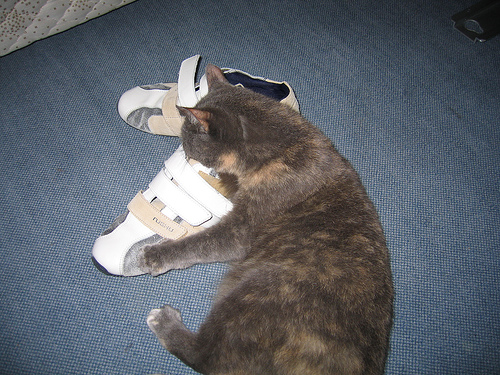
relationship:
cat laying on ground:
[134, 62, 397, 375] [7, 4, 496, 374]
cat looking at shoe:
[141, 62, 397, 373] [98, 140, 230, 269]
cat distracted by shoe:
[141, 62, 397, 373] [91, 140, 241, 282]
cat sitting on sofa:
[141, 62, 397, 373] [1, 0, 498, 374]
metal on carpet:
[451, 10, 488, 50] [2, 0, 499, 375]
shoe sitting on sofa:
[90, 144, 245, 277] [2, 54, 499, 372]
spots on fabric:
[9, 16, 20, 26] [0, 0, 130, 57]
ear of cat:
[174, 104, 216, 134] [126, 55, 405, 371]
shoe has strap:
[90, 144, 245, 277] [126, 189, 187, 241]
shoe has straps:
[115, 54, 302, 132] [165, 53, 220, 108]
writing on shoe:
[152, 216, 174, 232] [91, 140, 241, 282]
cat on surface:
[141, 62, 397, 373] [0, 2, 499, 372]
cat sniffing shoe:
[141, 62, 397, 373] [175, 90, 396, 373]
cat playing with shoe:
[141, 62, 397, 373] [90, 144, 245, 277]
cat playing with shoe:
[141, 62, 397, 373] [115, 54, 303, 138]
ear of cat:
[176, 105, 216, 135] [141, 62, 397, 373]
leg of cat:
[140, 207, 246, 277] [141, 62, 397, 373]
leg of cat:
[144, 303, 203, 368] [141, 62, 397, 373]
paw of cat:
[141, 238, 185, 277] [130, 74, 418, 374]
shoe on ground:
[85, 144, 246, 272] [360, 26, 477, 158]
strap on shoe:
[129, 180, 200, 234] [90, 144, 245, 277]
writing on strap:
[151, 215, 181, 237] [124, 188, 186, 243]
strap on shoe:
[122, 150, 234, 239] [82, 148, 235, 283]